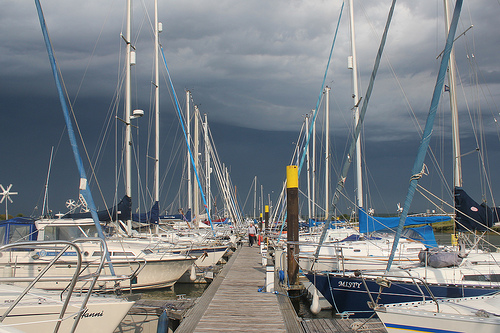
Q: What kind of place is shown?
A: It is a marina.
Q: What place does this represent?
A: It represents the marina.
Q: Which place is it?
A: It is a marina.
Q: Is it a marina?
A: Yes, it is a marina.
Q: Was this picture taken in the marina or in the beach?
A: It was taken at the marina.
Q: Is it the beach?
A: No, it is the marina.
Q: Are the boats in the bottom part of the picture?
A: Yes, the boats are in the bottom of the image.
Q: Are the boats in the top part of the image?
A: No, the boats are in the bottom of the image.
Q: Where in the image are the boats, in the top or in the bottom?
A: The boats are in the bottom of the image.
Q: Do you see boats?
A: Yes, there is a boat.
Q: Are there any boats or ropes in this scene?
A: Yes, there is a boat.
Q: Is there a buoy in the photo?
A: No, there are no buoys.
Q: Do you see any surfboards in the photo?
A: No, there are no surfboards.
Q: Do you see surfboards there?
A: No, there are no surfboards.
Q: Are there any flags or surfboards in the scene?
A: No, there are no surfboards or flags.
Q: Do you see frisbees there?
A: No, there are no frisbees.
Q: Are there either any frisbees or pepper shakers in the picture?
A: No, there are no frisbees or pepper shakers.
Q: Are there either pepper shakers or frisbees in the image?
A: No, there are no frisbees or pepper shakers.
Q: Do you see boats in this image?
A: Yes, there is a boat.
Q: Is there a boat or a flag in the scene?
A: Yes, there is a boat.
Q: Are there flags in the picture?
A: No, there are no flags.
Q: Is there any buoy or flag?
A: No, there are no flags or buoys.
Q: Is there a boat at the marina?
A: Yes, there is a boat at the marina.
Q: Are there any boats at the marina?
A: Yes, there is a boat at the marina.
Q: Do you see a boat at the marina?
A: Yes, there is a boat at the marina.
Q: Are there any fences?
A: No, there are no fences.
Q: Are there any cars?
A: No, there are no cars.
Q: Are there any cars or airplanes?
A: No, there are no cars or airplanes.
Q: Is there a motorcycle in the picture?
A: No, there are no motorcycles.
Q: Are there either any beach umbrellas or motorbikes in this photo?
A: No, there are no motorbikes or beach umbrellas.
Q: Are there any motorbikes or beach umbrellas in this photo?
A: No, there are no motorbikes or beach umbrellas.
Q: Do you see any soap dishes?
A: No, there are no soap dishes.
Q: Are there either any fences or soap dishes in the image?
A: No, there are no soap dishes or fences.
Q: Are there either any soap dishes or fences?
A: No, there are no soap dishes or fences.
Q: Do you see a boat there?
A: Yes, there is a boat.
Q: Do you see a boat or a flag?
A: Yes, there is a boat.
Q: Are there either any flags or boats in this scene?
A: Yes, there is a boat.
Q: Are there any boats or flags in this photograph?
A: Yes, there is a boat.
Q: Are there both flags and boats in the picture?
A: No, there is a boat but no flags.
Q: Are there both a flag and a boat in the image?
A: No, there is a boat but no flags.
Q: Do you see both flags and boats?
A: No, there is a boat but no flags.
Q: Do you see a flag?
A: No, there are no flags.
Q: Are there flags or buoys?
A: No, there are no flags or buoys.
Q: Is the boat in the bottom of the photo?
A: Yes, the boat is in the bottom of the image.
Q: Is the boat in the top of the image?
A: No, the boat is in the bottom of the image.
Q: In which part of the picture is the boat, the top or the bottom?
A: The boat is in the bottom of the image.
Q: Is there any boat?
A: Yes, there is a boat.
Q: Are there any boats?
A: Yes, there is a boat.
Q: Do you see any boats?
A: Yes, there is a boat.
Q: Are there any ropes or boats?
A: Yes, there is a boat.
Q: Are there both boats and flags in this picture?
A: No, there is a boat but no flags.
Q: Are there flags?
A: No, there are no flags.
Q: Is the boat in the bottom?
A: Yes, the boat is in the bottom of the image.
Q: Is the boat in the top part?
A: No, the boat is in the bottom of the image.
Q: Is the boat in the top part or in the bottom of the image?
A: The boat is in the bottom of the image.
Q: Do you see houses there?
A: No, there are no houses.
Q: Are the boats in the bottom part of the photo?
A: Yes, the boats are in the bottom of the image.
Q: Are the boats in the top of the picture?
A: No, the boats are in the bottom of the image.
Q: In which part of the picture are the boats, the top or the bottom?
A: The boats are in the bottom of the image.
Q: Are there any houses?
A: No, there are no houses.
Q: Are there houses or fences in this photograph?
A: No, there are no houses or fences.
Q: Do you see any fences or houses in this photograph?
A: No, there are no houses or fences.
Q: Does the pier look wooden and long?
A: Yes, the pier is wooden and long.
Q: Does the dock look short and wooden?
A: No, the dock is wooden but long.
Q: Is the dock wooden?
A: Yes, the dock is wooden.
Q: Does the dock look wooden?
A: Yes, the dock is wooden.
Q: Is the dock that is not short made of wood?
A: Yes, the pier is made of wood.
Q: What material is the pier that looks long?
A: The dock is made of wood.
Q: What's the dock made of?
A: The dock is made of wood.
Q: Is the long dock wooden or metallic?
A: The dock is wooden.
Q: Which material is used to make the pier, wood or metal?
A: The pier is made of wood.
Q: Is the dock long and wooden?
A: Yes, the dock is long and wooden.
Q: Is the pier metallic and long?
A: No, the pier is long but wooden.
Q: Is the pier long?
A: Yes, the pier is long.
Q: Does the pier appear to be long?
A: Yes, the pier is long.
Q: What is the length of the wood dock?
A: The pier is long.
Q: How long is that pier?
A: The pier is long.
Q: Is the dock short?
A: No, the dock is long.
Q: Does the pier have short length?
A: No, the pier is long.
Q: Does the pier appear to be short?
A: No, the pier is long.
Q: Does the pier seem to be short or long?
A: The pier is long.